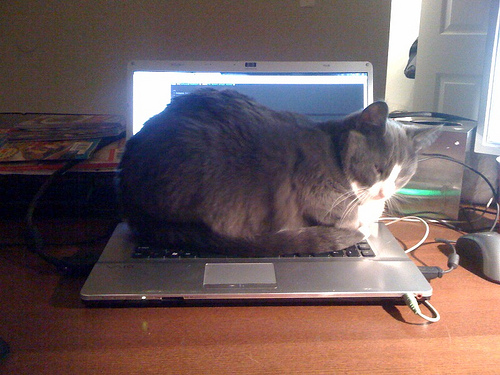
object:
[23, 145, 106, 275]
cable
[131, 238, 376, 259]
keyboard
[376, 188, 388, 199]
nose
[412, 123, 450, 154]
ears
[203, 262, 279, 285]
mouse pad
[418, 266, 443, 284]
usb plug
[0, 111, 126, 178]
magazines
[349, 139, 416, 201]
face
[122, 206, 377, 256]
tail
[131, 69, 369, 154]
computer light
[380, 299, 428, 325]
shadow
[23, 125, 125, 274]
cord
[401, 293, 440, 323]
cord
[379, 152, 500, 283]
cord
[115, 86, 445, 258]
cat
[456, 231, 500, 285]
mouse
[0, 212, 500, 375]
desk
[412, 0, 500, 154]
door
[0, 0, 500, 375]
room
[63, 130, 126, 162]
cable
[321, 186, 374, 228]
whiskers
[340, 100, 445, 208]
head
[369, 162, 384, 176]
eye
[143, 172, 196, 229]
leg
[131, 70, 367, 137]
screen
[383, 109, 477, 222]
shredder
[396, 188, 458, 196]
light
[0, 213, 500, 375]
table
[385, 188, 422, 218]
whiskers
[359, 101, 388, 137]
ear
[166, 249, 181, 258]
button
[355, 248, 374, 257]
button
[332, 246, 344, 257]
button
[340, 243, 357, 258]
button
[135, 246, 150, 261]
button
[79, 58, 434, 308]
computer